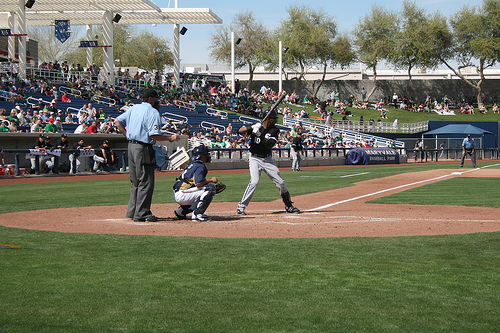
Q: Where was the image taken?
A: It was taken at the field.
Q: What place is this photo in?
A: It is at the field.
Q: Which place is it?
A: It is a field.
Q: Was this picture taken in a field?
A: Yes, it was taken in a field.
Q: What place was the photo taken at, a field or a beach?
A: It was taken at a field.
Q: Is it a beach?
A: No, it is a field.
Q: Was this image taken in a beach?
A: No, the picture was taken in a field.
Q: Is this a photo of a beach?
A: No, the picture is showing a field.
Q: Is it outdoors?
A: Yes, it is outdoors.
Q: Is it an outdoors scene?
A: Yes, it is outdoors.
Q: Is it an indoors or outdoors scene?
A: It is outdoors.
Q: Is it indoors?
A: No, it is outdoors.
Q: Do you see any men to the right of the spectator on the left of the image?
A: Yes, there are men to the right of the spectator.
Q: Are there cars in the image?
A: No, there are no cars.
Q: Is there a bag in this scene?
A: No, there are no bags.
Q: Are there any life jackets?
A: No, there are no life jackets.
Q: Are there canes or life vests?
A: No, there are no life vests or canes.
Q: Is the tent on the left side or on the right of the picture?
A: The tent is on the right of the image.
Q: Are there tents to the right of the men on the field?
A: Yes, there is a tent to the right of the men.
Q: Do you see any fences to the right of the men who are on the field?
A: No, there is a tent to the right of the men.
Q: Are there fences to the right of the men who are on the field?
A: No, there is a tent to the right of the men.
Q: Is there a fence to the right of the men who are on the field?
A: No, there is a tent to the right of the men.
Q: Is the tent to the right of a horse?
A: No, the tent is to the right of a person.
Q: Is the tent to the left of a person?
A: No, the tent is to the right of a person.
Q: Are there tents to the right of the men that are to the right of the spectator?
A: Yes, there is a tent to the right of the men.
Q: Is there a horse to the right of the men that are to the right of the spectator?
A: No, there is a tent to the right of the men.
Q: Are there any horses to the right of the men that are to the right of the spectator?
A: No, there is a tent to the right of the men.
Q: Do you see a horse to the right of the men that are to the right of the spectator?
A: No, there is a tent to the right of the men.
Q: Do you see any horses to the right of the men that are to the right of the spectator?
A: No, there is a tent to the right of the men.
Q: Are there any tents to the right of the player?
A: Yes, there is a tent to the right of the player.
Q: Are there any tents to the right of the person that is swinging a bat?
A: Yes, there is a tent to the right of the player.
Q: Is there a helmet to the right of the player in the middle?
A: No, there is a tent to the right of the player.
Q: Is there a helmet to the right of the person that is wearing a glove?
A: No, there is a tent to the right of the player.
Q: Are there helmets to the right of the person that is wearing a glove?
A: No, there is a tent to the right of the player.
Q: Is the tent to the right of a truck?
A: No, the tent is to the right of the player.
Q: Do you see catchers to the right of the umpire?
A: Yes, there is a catcher to the right of the umpire.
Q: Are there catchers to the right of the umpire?
A: Yes, there is a catcher to the right of the umpire.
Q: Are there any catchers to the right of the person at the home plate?
A: Yes, there is a catcher to the right of the umpire.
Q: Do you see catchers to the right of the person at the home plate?
A: Yes, there is a catcher to the right of the umpire.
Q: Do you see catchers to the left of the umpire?
A: No, the catcher is to the right of the umpire.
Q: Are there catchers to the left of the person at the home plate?
A: No, the catcher is to the right of the umpire.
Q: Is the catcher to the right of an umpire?
A: Yes, the catcher is to the right of an umpire.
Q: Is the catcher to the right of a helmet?
A: No, the catcher is to the right of an umpire.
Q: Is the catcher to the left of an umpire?
A: No, the catcher is to the right of an umpire.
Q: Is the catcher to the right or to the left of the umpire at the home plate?
A: The catcher is to the right of the umpire.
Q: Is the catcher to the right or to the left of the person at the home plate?
A: The catcher is to the right of the umpire.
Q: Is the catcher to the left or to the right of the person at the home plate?
A: The catcher is to the right of the umpire.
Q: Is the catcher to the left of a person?
A: Yes, the catcher is to the left of a person.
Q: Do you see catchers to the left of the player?
A: Yes, there is a catcher to the left of the player.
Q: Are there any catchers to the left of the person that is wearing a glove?
A: Yes, there is a catcher to the left of the player.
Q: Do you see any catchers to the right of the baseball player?
A: No, the catcher is to the left of the player.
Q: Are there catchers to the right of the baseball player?
A: No, the catcher is to the left of the player.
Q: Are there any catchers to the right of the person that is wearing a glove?
A: No, the catcher is to the left of the player.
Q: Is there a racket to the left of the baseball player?
A: No, there is a catcher to the left of the player.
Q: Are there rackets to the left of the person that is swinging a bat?
A: No, there is a catcher to the left of the player.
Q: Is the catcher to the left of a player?
A: Yes, the catcher is to the left of a player.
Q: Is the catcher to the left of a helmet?
A: No, the catcher is to the left of a player.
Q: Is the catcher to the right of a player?
A: No, the catcher is to the left of a player.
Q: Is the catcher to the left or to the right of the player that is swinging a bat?
A: The catcher is to the left of the player.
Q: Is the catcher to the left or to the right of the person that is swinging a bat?
A: The catcher is to the left of the player.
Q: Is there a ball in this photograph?
A: No, there are no balls.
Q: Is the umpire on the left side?
A: Yes, the umpire is on the left of the image.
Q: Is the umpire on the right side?
A: No, the umpire is on the left of the image.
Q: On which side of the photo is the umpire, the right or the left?
A: The umpire is on the left of the image.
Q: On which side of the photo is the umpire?
A: The umpire is on the left of the image.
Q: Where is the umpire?
A: The umpire is at the home plate.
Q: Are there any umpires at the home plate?
A: Yes, there is an umpire at the home plate.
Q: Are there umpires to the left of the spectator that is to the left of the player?
A: Yes, there is an umpire to the left of the spectator.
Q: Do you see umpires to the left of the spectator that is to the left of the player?
A: Yes, there is an umpire to the left of the spectator.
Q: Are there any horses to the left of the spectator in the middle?
A: No, there is an umpire to the left of the spectator.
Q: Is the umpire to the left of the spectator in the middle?
A: Yes, the umpire is to the left of the spectator.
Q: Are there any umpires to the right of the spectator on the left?
A: Yes, there is an umpire to the right of the spectator.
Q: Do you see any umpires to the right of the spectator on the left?
A: Yes, there is an umpire to the right of the spectator.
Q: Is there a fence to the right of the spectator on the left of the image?
A: No, there is an umpire to the right of the spectator.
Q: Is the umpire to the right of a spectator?
A: Yes, the umpire is to the right of a spectator.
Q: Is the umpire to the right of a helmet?
A: No, the umpire is to the right of a spectator.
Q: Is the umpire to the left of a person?
A: Yes, the umpire is to the left of a person.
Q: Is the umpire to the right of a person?
A: No, the umpire is to the left of a person.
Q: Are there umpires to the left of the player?
A: Yes, there is an umpire to the left of the player.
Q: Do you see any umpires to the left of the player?
A: Yes, there is an umpire to the left of the player.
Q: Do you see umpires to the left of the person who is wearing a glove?
A: Yes, there is an umpire to the left of the player.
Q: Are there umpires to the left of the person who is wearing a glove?
A: Yes, there is an umpire to the left of the player.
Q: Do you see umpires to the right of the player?
A: No, the umpire is to the left of the player.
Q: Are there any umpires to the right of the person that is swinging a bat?
A: No, the umpire is to the left of the player.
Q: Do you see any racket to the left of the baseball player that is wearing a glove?
A: No, there is an umpire to the left of the player.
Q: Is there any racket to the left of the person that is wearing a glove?
A: No, there is an umpire to the left of the player.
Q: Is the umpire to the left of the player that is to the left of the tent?
A: Yes, the umpire is to the left of the player.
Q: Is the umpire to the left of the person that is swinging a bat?
A: Yes, the umpire is to the left of the player.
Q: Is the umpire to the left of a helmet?
A: No, the umpire is to the left of the player.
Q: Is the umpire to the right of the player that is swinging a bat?
A: No, the umpire is to the left of the player.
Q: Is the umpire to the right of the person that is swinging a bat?
A: No, the umpire is to the left of the player.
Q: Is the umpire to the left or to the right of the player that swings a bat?
A: The umpire is to the left of the player.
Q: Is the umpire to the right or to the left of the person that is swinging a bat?
A: The umpire is to the left of the player.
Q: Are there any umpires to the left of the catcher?
A: Yes, there is an umpire to the left of the catcher.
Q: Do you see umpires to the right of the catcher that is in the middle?
A: No, the umpire is to the left of the catcher.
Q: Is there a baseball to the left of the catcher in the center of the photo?
A: No, there is an umpire to the left of the catcher.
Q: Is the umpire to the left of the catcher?
A: Yes, the umpire is to the left of the catcher.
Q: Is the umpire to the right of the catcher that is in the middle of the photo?
A: No, the umpire is to the left of the catcher.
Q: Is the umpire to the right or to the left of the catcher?
A: The umpire is to the left of the catcher.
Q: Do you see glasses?
A: No, there are no glasses.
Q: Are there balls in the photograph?
A: No, there are no balls.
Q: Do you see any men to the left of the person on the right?
A: Yes, there are men to the left of the person.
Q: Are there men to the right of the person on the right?
A: No, the men are to the left of the person.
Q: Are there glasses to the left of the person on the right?
A: No, there are men to the left of the person.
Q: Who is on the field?
A: The men are on the field.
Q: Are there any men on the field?
A: Yes, there are men on the field.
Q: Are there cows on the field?
A: No, there are men on the field.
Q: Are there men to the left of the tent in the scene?
A: Yes, there are men to the left of the tent.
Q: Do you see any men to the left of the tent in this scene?
A: Yes, there are men to the left of the tent.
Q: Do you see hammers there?
A: No, there are no hammers.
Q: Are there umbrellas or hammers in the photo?
A: No, there are no hammers or umbrellas.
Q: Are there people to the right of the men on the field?
A: Yes, there is a person to the right of the men.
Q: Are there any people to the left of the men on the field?
A: No, the person is to the right of the men.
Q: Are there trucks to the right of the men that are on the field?
A: No, there is a person to the right of the men.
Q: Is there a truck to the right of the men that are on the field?
A: No, there is a person to the right of the men.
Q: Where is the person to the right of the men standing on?
A: The person is standing on the field.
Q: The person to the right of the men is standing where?
A: The person is standing on the field.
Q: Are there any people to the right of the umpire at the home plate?
A: Yes, there is a person to the right of the umpire.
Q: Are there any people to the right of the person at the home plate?
A: Yes, there is a person to the right of the umpire.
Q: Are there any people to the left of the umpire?
A: No, the person is to the right of the umpire.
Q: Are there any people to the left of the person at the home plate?
A: No, the person is to the right of the umpire.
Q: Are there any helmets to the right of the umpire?
A: No, there is a person to the right of the umpire.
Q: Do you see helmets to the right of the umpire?
A: No, there is a person to the right of the umpire.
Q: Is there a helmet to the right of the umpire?
A: No, there is a person to the right of the umpire.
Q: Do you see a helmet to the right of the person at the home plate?
A: No, there is a person to the right of the umpire.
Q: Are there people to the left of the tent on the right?
A: Yes, there is a person to the left of the tent.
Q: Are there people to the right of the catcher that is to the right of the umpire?
A: Yes, there is a person to the right of the catcher.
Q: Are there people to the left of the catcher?
A: No, the person is to the right of the catcher.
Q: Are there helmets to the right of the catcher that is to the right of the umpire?
A: No, there is a person to the right of the catcher.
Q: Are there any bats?
A: Yes, there is a bat.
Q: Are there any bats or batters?
A: Yes, there is a bat.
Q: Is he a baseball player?
A: Yes, this is a baseball player.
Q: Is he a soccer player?
A: No, this is a baseball player.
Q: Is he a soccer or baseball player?
A: This is a baseball player.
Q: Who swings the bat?
A: The player swings the bat.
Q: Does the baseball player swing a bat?
A: Yes, the player swings a bat.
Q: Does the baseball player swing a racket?
A: No, the player swings a bat.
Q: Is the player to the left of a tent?
A: Yes, the player is to the left of a tent.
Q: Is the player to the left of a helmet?
A: No, the player is to the left of a tent.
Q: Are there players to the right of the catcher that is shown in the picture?
A: Yes, there is a player to the right of the catcher.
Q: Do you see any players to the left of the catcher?
A: No, the player is to the right of the catcher.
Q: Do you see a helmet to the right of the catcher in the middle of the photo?
A: No, there is a player to the right of the catcher.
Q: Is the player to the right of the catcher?
A: Yes, the player is to the right of the catcher.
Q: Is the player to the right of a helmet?
A: No, the player is to the right of the catcher.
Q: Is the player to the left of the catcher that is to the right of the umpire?
A: No, the player is to the right of the catcher.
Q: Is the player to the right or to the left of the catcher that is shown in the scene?
A: The player is to the right of the catcher.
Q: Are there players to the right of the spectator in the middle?
A: Yes, there is a player to the right of the spectator.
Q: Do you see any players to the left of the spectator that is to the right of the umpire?
A: No, the player is to the right of the spectator.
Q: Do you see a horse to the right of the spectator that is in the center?
A: No, there is a player to the right of the spectator.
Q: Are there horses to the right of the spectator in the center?
A: No, there is a player to the right of the spectator.